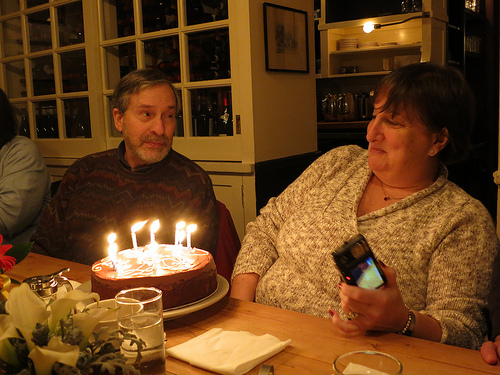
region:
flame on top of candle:
[126, 216, 148, 233]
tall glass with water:
[116, 290, 168, 363]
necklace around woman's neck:
[377, 183, 396, 204]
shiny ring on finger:
[341, 309, 358, 322]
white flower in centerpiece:
[6, 284, 46, 337]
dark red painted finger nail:
[326, 305, 333, 315]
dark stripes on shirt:
[151, 178, 196, 203]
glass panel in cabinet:
[188, 84, 238, 137]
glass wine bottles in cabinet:
[192, 90, 232, 132]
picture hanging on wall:
[258, 0, 312, 80]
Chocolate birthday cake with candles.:
[92, 219, 217, 309]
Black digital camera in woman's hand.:
[331, 233, 387, 293]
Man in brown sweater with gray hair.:
[27, 68, 217, 257]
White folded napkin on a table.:
[165, 326, 291, 373]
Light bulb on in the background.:
[361, 20, 379, 31]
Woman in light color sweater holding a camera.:
[229, 64, 496, 347]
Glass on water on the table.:
[116, 286, 166, 372]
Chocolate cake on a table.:
[91, 218, 217, 310]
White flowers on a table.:
[1, 283, 142, 373]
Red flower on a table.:
[0, 233, 17, 279]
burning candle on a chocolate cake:
[182, 221, 202, 253]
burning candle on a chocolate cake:
[173, 225, 188, 262]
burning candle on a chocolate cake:
[168, 215, 190, 247]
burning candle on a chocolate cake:
[145, 217, 163, 246]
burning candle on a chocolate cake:
[127, 213, 149, 252]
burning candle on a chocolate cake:
[106, 230, 119, 248]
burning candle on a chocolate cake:
[105, 240, 122, 275]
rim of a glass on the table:
[327, 343, 409, 373]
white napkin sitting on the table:
[162, 321, 294, 373]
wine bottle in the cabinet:
[215, 92, 233, 137]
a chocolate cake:
[90, 242, 215, 307]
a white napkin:
[160, 322, 290, 372]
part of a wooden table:
[160, 295, 495, 370]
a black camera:
[330, 235, 387, 290]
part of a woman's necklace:
[375, 176, 407, 206]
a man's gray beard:
[120, 131, 169, 161]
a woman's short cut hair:
[370, 61, 473, 138]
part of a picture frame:
[264, 19, 316, 81]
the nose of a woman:
[365, 109, 385, 144]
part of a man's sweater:
[30, 145, 216, 272]